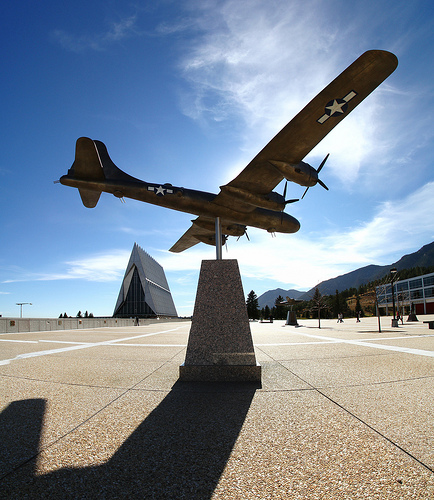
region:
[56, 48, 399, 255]
an airplane on a pedestal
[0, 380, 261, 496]
the shadow of an airplane on the ground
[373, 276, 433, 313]
a glass windowed building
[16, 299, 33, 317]
a lamp post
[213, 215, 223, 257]
a pole holding up an airplane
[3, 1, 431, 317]
a blue sky with white clouds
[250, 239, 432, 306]
mountains in the distance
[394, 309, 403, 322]
a person in a red shirt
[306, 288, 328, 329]
a tree in a plaza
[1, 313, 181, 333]
a wall along a plaza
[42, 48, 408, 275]
monument of a plane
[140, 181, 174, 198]
star on the body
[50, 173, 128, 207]
guns on the plane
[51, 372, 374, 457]
lines on the sidewalk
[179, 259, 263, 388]
the stone base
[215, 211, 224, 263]
the pole holding the plane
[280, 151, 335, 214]
th plane propellers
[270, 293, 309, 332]
another plane monument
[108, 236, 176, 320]
a pyramid shaped building.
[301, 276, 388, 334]
trees in planters on the pavement.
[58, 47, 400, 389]
propeller plane model on granite base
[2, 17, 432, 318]
blue sky with wispy white clouds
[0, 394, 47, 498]
shadow of airplane wing on granite walkway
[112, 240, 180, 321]
triangular glass building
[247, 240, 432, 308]
mountains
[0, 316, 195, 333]
low concrete wall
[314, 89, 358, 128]
blue and white U.S. Air Force logo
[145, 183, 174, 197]
blue and white U.S. Air Force symbol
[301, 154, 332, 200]
rightmost propeller of airplane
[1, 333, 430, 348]
white line stretching across granite walkway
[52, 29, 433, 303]
an airplane in the air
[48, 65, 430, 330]
a plane in the air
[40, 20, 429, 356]
a statue of an airplane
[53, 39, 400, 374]
a statue of a plane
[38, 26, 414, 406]
a tall plan statue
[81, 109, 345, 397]
plane on top of a pole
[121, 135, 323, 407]
plane pole and cement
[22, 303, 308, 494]
shadow of a plane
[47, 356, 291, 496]
shadow of an airplane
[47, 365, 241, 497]
shadow of a statue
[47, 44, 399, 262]
The plane on display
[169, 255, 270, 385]
The base under the plane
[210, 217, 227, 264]
The pole under the plane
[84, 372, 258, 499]
The shadow of the planes base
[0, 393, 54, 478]
The shadow of the wings plane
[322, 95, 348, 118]
The star on the plane's wing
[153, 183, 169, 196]
The star on the side of the plane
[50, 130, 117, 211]
The tail of the plane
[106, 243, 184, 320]
The triangular building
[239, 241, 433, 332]
The mountains on the right